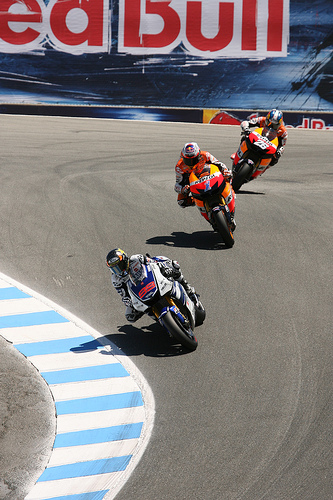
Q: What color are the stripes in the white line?
A: Blue.